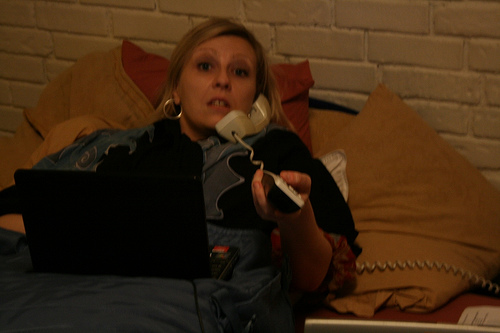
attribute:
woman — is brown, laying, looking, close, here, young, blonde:
[138, 31, 346, 262]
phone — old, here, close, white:
[217, 89, 283, 151]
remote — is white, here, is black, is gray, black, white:
[253, 163, 309, 217]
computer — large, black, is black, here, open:
[20, 160, 237, 280]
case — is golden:
[325, 77, 496, 313]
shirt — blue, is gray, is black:
[4, 112, 361, 331]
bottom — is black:
[262, 179, 300, 217]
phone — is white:
[216, 91, 274, 141]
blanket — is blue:
[0, 221, 307, 331]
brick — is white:
[365, 29, 467, 68]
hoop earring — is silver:
[163, 95, 183, 119]